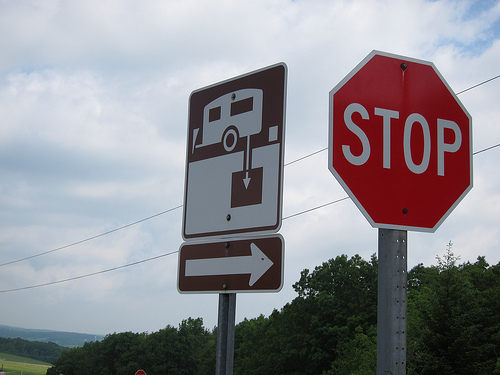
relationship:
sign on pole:
[182, 61, 287, 246] [212, 291, 237, 373]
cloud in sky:
[1, 66, 177, 168] [3, 4, 469, 349]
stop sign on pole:
[328, 48, 474, 233] [376, 231, 411, 370]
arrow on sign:
[183, 241, 274, 286] [175, 228, 287, 297]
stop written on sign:
[338, 102, 463, 179] [328, 49, 473, 233]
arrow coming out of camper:
[227, 137, 270, 197] [189, 96, 269, 156]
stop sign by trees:
[328, 48, 474, 233] [278, 244, 375, 373]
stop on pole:
[341, 102, 462, 176] [376, 231, 411, 370]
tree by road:
[407, 267, 486, 367] [21, 350, 185, 372]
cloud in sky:
[1, 66, 177, 168] [3, 2, 498, 324]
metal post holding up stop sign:
[376, 227, 408, 373] [328, 48, 474, 233]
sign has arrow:
[174, 232, 285, 292] [183, 241, 274, 286]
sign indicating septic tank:
[182, 61, 287, 246] [204, 102, 266, 213]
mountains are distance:
[7, 313, 122, 374] [21, 123, 497, 322]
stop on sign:
[341, 102, 462, 176] [321, 31, 481, 251]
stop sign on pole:
[328, 48, 474, 233] [377, 228, 407, 373]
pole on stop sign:
[377, 228, 407, 373] [328, 48, 474, 233]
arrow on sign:
[184, 242, 273, 286] [180, 230, 286, 291]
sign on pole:
[182, 62, 287, 241] [212, 282, 239, 372]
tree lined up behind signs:
[407, 255, 486, 375] [178, 62, 287, 292]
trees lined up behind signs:
[289, 254, 374, 366] [329, 48, 474, 231]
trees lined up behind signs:
[215, 316, 276, 372] [329, 48, 474, 231]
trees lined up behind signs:
[115, 326, 197, 372] [329, 48, 474, 231]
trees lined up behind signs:
[48, 337, 108, 372] [178, 62, 287, 292]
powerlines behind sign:
[28, 196, 205, 304] [299, 71, 487, 252]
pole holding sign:
[377, 228, 407, 373] [312, 40, 487, 230]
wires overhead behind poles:
[4, 199, 181, 299] [205, 229, 432, 373]